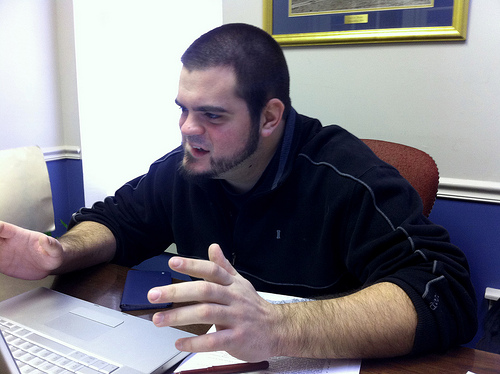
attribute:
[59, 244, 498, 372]
table — brown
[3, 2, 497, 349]
painted wall — white, blue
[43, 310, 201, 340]
trackpad — white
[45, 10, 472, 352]
man — white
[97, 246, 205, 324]
book — little, black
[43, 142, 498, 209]
rail — chair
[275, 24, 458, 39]
frame — golden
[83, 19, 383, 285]
brunette man — brunnette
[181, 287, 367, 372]
paper — white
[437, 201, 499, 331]
wall — blue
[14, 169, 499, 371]
desk — wooden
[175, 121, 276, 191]
beard — trimmed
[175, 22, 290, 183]
head — shaved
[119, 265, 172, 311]
book — blue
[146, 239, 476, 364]
arm — hairy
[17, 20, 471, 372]
man — sitting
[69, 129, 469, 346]
sweater — dark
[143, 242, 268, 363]
hand — clean